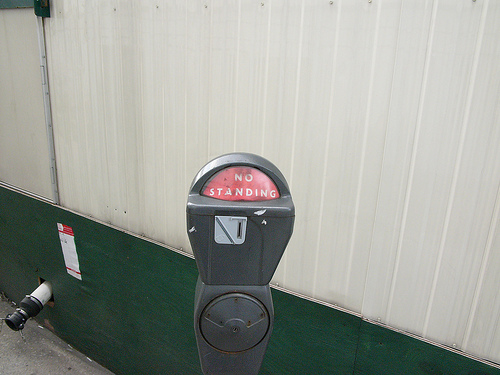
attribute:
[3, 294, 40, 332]
end — black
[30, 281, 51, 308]
pipe — white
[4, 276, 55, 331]
pipe — white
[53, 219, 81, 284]
sticker —  white and red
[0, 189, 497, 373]
board —  green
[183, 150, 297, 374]
meter — red and white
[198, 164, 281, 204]
sign — red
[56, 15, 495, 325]
panels — white, vertical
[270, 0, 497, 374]
wall — low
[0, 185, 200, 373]
lower wall — green, wooden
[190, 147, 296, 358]
parking meter — expired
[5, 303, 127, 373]
concrete — gray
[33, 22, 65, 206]
rail — metal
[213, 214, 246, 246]
coin slot — single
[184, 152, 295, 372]
parking meter — red and gray, expired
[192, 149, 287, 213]
sign — red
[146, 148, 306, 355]
parking meter — dark grey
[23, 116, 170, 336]
wall — white, green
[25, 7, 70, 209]
pipe — gray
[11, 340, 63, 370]
sidewalk — grey, cement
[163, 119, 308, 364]
parking meter — red, grey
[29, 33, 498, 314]
wall — green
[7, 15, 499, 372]
wall —  white, white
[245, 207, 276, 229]
marks — white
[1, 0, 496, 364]
siding — metal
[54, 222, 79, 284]
sign — red, white